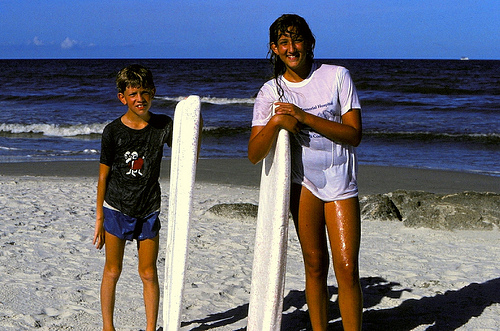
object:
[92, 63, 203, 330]
person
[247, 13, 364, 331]
person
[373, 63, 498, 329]
beach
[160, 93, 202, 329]
surfboard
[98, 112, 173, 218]
shirt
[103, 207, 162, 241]
shorts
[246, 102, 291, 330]
surfboard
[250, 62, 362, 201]
shirt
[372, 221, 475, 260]
rocks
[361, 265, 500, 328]
shadow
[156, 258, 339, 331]
shadow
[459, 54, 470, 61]
boat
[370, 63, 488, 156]
water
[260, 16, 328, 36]
hair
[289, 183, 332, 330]
leg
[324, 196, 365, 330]
leg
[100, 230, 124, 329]
leg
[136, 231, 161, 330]
leg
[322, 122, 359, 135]
arm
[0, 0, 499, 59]
sky